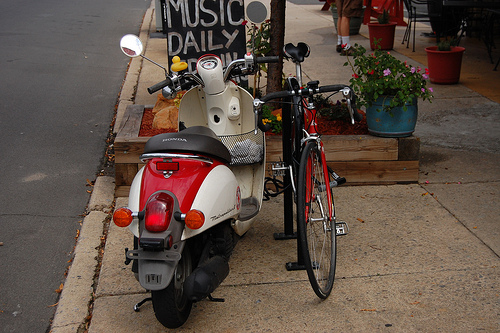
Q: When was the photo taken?
A: Daytime.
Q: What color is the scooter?
A: Red and white.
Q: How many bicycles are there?
A: One.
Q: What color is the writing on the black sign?
A: White.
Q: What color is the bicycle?
A: Red.